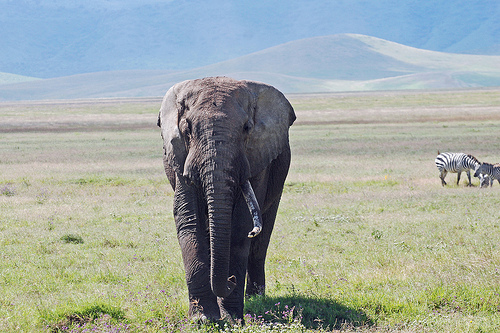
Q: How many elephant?
A: 1.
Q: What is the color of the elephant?
A: Grey.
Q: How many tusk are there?
A: 1.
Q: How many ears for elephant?
A: 2.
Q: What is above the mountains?
A: The sky.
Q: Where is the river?
A: Near the mountains.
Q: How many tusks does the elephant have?
A: One.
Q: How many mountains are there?
A: One.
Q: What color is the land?
A: Brown.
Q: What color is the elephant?
A: Grey.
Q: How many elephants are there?
A: One.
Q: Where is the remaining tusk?
A: On the left.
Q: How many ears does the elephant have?
A: Two.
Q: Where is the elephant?
A: Open field.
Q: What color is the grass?
A: Green.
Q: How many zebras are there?
A: Two.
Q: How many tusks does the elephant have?
A: One.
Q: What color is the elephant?
A: Brown.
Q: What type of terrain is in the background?
A: Hills.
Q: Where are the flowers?
A: To the right of the elephant.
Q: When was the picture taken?
A: Daytime.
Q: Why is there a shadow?
A: It is daytime.